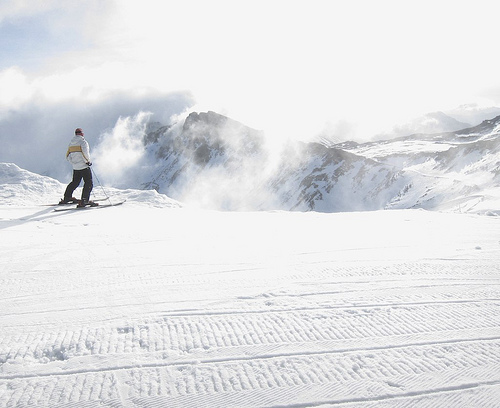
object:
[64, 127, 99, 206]
man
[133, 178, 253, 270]
cliff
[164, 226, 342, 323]
snow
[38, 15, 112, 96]
sky